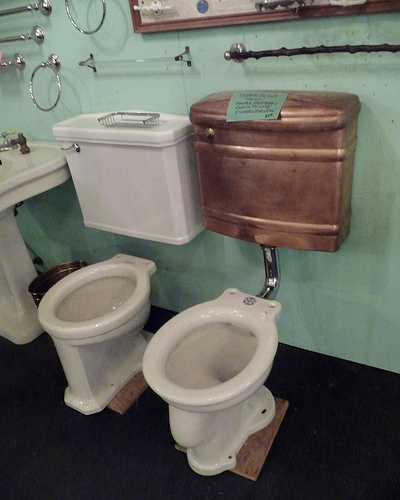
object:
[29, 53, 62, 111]
ring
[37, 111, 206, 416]
toilet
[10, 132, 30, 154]
handle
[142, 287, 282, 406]
lid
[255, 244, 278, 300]
frame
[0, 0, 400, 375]
wall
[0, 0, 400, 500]
bathroom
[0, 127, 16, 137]
knob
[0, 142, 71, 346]
sink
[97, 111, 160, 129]
tray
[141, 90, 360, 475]
toilet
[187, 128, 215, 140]
handle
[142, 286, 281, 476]
shadow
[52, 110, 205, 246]
tank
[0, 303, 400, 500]
floor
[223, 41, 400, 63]
rack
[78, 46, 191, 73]
bar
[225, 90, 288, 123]
paper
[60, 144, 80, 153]
handle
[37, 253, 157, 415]
tank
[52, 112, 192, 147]
lid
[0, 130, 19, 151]
faucet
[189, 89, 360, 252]
tank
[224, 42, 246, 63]
handle